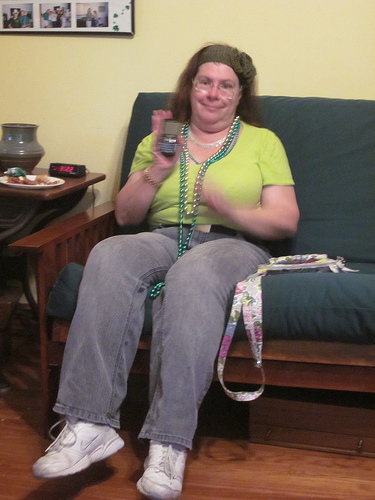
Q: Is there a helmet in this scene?
A: No, there are no helmets.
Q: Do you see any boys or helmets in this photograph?
A: No, there are no helmets or boys.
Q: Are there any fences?
A: No, there are no fences.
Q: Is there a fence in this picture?
A: No, there are no fences.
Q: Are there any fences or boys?
A: No, there are no fences or boys.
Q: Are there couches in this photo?
A: Yes, there is a couch.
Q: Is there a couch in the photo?
A: Yes, there is a couch.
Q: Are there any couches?
A: Yes, there is a couch.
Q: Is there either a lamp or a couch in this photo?
A: Yes, there is a couch.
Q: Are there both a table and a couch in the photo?
A: Yes, there are both a couch and a table.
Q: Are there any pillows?
A: No, there are no pillows.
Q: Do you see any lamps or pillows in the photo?
A: No, there are no pillows or lamps.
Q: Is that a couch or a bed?
A: That is a couch.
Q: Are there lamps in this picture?
A: No, there are no lamps.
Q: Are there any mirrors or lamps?
A: No, there are no lamps or mirrors.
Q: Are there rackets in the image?
A: No, there are no rackets.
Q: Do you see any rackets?
A: No, there are no rackets.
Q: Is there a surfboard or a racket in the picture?
A: No, there are no rackets or surfboards.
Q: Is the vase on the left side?
A: Yes, the vase is on the left of the image.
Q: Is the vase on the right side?
A: No, the vase is on the left of the image.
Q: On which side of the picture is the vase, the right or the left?
A: The vase is on the left of the image.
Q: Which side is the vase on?
A: The vase is on the left of the image.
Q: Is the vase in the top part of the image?
A: Yes, the vase is in the top of the image.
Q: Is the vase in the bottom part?
A: No, the vase is in the top of the image.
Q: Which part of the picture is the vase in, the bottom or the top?
A: The vase is in the top of the image.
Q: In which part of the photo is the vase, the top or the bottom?
A: The vase is in the top of the image.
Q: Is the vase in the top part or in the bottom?
A: The vase is in the top of the image.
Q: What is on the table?
A: The vase is on the table.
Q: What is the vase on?
A: The vase is on the table.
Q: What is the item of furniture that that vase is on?
A: The piece of furniture is a table.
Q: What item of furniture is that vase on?
A: The vase is on the table.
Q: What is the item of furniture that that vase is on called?
A: The piece of furniture is a table.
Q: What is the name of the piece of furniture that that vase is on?
A: The piece of furniture is a table.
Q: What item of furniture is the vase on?
A: The vase is on the table.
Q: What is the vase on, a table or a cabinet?
A: The vase is on a table.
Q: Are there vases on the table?
A: Yes, there is a vase on the table.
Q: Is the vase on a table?
A: Yes, the vase is on a table.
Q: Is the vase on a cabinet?
A: No, the vase is on a table.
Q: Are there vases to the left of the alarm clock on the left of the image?
A: Yes, there is a vase to the left of the alarm clock.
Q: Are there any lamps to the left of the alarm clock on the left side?
A: No, there is a vase to the left of the alarm clock.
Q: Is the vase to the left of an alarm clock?
A: Yes, the vase is to the left of an alarm clock.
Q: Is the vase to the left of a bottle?
A: No, the vase is to the left of an alarm clock.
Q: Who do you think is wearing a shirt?
A: The lady is wearing a shirt.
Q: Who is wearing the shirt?
A: The lady is wearing a shirt.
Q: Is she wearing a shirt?
A: Yes, the lady is wearing a shirt.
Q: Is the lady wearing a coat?
A: No, the lady is wearing a shirt.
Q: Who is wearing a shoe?
A: The lady is wearing a shoe.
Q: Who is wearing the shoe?
A: The lady is wearing a shoe.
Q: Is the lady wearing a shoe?
A: Yes, the lady is wearing a shoe.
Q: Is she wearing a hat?
A: No, the lady is wearing a shoe.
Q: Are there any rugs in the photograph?
A: No, there are no rugs.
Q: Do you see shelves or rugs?
A: No, there are no rugs or shelves.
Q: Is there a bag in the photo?
A: Yes, there is a bag.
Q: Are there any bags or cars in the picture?
A: Yes, there is a bag.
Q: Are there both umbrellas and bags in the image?
A: No, there is a bag but no umbrellas.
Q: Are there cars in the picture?
A: No, there are no cars.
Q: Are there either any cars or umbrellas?
A: No, there are no cars or umbrellas.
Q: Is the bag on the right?
A: Yes, the bag is on the right of the image.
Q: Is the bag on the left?
A: No, the bag is on the right of the image.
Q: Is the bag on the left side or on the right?
A: The bag is on the right of the image.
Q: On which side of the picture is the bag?
A: The bag is on the right of the image.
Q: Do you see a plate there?
A: Yes, there is a plate.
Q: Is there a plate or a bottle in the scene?
A: Yes, there is a plate.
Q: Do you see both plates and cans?
A: No, there is a plate but no cans.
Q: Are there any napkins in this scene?
A: No, there are no napkins.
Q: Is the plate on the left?
A: Yes, the plate is on the left of the image.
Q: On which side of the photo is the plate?
A: The plate is on the left of the image.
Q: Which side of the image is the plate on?
A: The plate is on the left of the image.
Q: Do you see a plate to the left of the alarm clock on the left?
A: Yes, there is a plate to the left of the alarm clock.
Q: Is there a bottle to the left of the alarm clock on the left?
A: No, there is a plate to the left of the alarm clock.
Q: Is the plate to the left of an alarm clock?
A: Yes, the plate is to the left of an alarm clock.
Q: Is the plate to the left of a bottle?
A: No, the plate is to the left of an alarm clock.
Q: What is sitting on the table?
A: The plate is sitting on the table.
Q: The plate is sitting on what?
A: The plate is sitting on the table.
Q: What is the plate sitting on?
A: The plate is sitting on the table.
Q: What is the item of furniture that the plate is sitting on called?
A: The piece of furniture is a table.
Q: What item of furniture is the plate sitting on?
A: The plate is sitting on the table.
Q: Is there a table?
A: Yes, there is a table.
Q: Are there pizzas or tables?
A: Yes, there is a table.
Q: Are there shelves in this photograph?
A: No, there are no shelves.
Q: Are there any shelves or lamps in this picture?
A: No, there are no shelves or lamps.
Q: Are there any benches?
A: No, there are no benches.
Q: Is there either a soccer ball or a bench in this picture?
A: No, there are no benches or soccer balls.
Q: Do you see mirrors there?
A: No, there are no mirrors.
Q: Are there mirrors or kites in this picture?
A: No, there are no mirrors or kites.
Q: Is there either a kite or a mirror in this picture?
A: No, there are no mirrors or kites.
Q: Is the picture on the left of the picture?
A: Yes, the picture is on the left of the image.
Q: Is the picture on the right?
A: No, the picture is on the left of the image.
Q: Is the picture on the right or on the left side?
A: The picture is on the left of the image.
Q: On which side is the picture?
A: The picture is on the left of the image.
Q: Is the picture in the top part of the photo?
A: Yes, the picture is in the top of the image.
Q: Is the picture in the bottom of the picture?
A: No, the picture is in the top of the image.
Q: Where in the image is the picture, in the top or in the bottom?
A: The picture is in the top of the image.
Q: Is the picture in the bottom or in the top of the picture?
A: The picture is in the top of the image.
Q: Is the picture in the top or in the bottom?
A: The picture is in the top of the image.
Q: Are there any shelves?
A: No, there are no shelves.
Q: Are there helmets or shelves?
A: No, there are no shelves or helmets.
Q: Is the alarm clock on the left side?
A: Yes, the alarm clock is on the left of the image.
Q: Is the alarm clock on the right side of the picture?
A: No, the alarm clock is on the left of the image.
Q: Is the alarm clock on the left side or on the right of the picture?
A: The alarm clock is on the left of the image.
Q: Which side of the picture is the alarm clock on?
A: The alarm clock is on the left of the image.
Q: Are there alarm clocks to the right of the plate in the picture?
A: Yes, there is an alarm clock to the right of the plate.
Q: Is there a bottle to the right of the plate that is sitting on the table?
A: No, there is an alarm clock to the right of the plate.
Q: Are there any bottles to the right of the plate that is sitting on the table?
A: No, there is an alarm clock to the right of the plate.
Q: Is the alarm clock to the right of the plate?
A: Yes, the alarm clock is to the right of the plate.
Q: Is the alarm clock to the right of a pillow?
A: No, the alarm clock is to the right of the plate.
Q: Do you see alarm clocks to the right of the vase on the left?
A: Yes, there is an alarm clock to the right of the vase.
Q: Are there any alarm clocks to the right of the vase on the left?
A: Yes, there is an alarm clock to the right of the vase.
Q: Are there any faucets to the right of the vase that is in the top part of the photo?
A: No, there is an alarm clock to the right of the vase.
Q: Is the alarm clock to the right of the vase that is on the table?
A: Yes, the alarm clock is to the right of the vase.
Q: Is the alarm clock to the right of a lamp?
A: No, the alarm clock is to the right of the vase.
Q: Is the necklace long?
A: Yes, the necklace is long.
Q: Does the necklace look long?
A: Yes, the necklace is long.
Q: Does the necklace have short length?
A: No, the necklace is long.